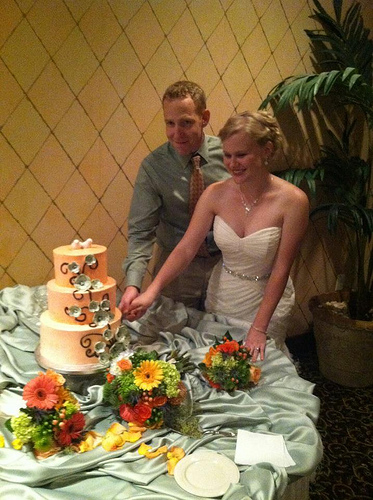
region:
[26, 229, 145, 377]
Beautiful three tier cake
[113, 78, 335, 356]
Happy couple on their wedding day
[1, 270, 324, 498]
Light green table cloth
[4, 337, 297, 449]
Three fresh flower bouquets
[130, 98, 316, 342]
The bride in white strapless gown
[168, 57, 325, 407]
this is a woman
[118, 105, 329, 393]
the woman is a bride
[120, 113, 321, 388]
woman wearing a wedding dress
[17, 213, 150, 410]
this is a cake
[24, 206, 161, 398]
the cake has 3 tiers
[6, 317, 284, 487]
bouquets on the table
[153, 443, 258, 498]
plate on the table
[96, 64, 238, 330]
this is a man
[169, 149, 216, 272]
man wearing a tie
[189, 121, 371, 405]
a bride wearing a dress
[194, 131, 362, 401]
a bride wearing a white dress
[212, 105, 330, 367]
a bride wearing a gown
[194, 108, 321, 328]
a brown wearing a necklace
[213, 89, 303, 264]
a woman with blonde hair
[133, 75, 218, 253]
a man wearing a shirt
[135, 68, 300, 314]
a man wearing a button down shirt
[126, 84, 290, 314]
a man wearing a tie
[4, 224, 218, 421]
a wedding cake on a plate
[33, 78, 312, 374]
bride and groom cutting a cake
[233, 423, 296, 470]
two white paper napkins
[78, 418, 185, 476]
yellow petals on a tablecloth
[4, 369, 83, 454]
bouquet of flowers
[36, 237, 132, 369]
three layer cake with silver flowers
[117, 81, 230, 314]
man wearing a gray dress shirt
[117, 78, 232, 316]
man wearing a tie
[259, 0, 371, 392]
large plant in a brown pot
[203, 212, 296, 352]
white dress with silver belt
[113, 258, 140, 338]
man and woman cutting a cake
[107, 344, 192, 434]
flowers on the table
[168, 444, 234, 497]
white plate on the table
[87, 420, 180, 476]
rose petals on the table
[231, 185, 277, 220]
woman wearing a necklace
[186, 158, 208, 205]
man wearing a brown tie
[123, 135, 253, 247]
man wearing a green shirt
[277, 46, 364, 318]
plant in the pot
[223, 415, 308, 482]
napkin on the table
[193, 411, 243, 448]
fork on the table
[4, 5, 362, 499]
a scene inside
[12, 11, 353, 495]
an image at a wedding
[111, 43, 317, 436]
two people posing for the camera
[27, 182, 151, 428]
a wedding cake